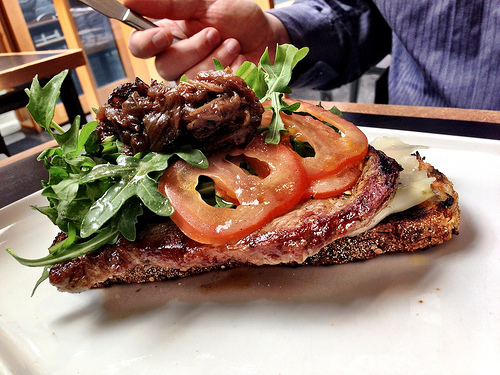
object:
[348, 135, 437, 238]
cheese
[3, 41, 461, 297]
meat dish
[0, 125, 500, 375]
plate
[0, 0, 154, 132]
wooden door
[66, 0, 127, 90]
glass panel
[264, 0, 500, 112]
shirt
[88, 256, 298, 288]
meat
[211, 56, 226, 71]
leaves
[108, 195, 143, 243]
leaves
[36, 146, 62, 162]
leaves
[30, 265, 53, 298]
leaves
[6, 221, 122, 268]
lettuce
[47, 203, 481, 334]
shadow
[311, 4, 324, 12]
button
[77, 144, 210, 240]
green lettuce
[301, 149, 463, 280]
meat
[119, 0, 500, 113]
man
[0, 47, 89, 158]
table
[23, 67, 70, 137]
greens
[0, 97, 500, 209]
table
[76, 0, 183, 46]
knife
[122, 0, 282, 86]
hand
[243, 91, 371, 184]
tomato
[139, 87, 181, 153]
mushrooms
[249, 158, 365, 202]
tomatoe slices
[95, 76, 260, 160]
meat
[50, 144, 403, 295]
bacon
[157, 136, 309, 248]
slices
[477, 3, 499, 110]
stripes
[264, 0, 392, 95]
sleeve